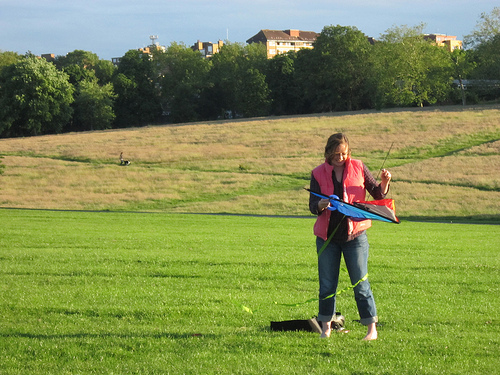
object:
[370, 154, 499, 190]
dead grass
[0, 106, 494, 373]
ground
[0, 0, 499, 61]
cloud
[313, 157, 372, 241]
vest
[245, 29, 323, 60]
buildings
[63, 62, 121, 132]
trees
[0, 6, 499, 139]
tree line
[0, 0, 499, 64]
sky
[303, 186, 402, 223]
kite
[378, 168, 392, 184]
hand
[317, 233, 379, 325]
pants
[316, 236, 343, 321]
leg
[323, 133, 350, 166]
hair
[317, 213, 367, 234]
waist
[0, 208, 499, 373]
grass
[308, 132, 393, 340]
woman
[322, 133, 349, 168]
head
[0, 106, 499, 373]
field